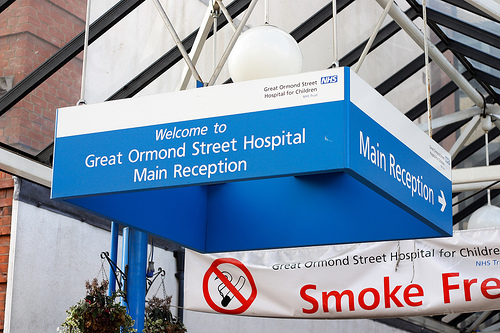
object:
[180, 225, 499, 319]
banner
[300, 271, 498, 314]
smoke free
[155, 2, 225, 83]
framework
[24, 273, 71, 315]
tarp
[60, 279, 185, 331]
baskets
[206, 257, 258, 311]
cross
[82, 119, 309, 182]
words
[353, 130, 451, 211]
direction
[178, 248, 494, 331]
wall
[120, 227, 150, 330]
pole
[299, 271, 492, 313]
letters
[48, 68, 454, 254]
box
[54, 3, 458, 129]
poles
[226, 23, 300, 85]
globe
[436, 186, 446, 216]
arrow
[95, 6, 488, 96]
panels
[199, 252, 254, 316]
circle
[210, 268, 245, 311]
cigarette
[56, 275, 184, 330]
bushes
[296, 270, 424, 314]
word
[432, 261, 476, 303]
letters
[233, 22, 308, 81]
light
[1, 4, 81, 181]
wall